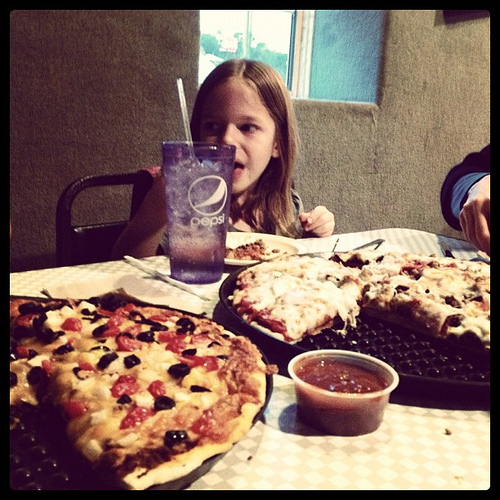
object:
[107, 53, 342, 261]
girl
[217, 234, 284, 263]
pizza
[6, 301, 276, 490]
pizza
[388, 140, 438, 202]
ground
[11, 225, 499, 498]
pizza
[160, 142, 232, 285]
glass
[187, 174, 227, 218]
logo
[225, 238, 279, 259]
slice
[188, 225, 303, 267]
plate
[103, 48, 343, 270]
girl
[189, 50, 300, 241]
hair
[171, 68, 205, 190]
straw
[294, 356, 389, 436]
sauce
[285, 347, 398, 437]
container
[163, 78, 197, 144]
straw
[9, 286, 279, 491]
pizza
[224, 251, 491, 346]
pizza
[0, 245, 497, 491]
table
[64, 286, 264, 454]
pizza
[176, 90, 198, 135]
straw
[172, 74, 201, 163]
drinking straw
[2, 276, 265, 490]
pizza pie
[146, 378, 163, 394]
tomatoe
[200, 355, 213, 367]
tomatoe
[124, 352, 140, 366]
olive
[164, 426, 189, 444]
olive